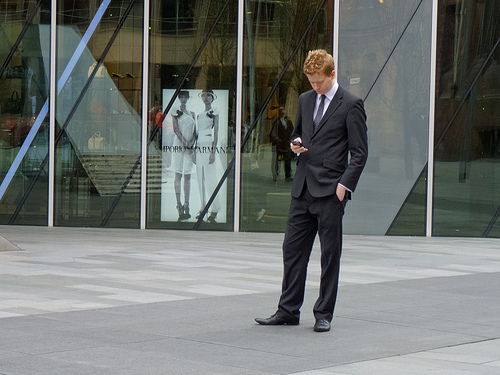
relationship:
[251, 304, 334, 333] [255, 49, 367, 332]
dress shoes on man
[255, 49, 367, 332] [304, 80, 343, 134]
man wearing white shirt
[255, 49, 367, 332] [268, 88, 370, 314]
man wearing suit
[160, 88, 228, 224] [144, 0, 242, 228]
advertisement in window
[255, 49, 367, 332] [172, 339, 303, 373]
man standing in street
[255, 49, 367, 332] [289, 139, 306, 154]
man looking at phone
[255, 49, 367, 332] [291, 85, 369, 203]
man wearing suit jacket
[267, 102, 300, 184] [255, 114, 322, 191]
reflection of person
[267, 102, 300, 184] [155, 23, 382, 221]
reflection in window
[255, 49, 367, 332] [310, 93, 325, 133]
man wearing tie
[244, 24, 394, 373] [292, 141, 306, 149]
man holding cell phone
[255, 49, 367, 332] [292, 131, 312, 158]
man holding cell phone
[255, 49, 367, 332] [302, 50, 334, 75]
man has short hair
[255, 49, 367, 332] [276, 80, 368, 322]
man wearing suit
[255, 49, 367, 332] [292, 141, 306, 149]
man looking at cell phone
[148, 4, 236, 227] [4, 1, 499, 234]
window in retail store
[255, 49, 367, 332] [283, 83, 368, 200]
man wearing jacket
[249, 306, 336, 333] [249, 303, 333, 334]
shoes on man's feet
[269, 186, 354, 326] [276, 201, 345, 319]
pants on man's legs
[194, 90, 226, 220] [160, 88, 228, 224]
woman on advertisement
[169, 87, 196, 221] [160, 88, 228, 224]
woman on advertisement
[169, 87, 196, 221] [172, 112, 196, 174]
woman wearing dress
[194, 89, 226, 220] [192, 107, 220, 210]
woman wearing suit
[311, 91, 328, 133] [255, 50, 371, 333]
tie on boy